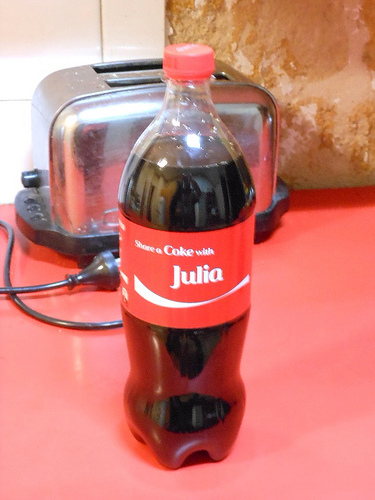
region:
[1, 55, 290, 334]
Toaster sitting on a red counter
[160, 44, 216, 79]
Red lid on Coke bottle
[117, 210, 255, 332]
Red and white label on Coke bottle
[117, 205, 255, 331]
Name on side of Coke bottle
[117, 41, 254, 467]
Coke bottle sitting on red counter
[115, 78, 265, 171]
Drops of Coke inside bottle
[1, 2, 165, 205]
White tiles on wall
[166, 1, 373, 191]
Brown backsplash behind toaster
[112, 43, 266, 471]
Clear plastic bottle sitting on counter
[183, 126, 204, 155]
Light reflection shining off of bottle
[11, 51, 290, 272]
chrome electrical toaster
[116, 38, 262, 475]
soda bottle with personalized label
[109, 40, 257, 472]
coca cola bottle is full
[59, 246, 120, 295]
electrical plug on a toaster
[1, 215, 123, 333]
black toaster cable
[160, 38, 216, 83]
red plastic lid of a soda bottle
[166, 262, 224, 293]
the name Julia printed on a soda bottle label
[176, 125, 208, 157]
light reflected in a soda bottle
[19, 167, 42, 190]
toast setting dial on a toaster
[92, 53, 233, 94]
slots in the top of a toaster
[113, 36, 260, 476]
A bottle of Coke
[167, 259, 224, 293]
The name "Julia" on a bottle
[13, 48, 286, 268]
Silver and black toaster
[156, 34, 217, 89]
A red bottle cap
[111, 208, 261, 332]
Red label on the bottle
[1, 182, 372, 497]
A red colored countertop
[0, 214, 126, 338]
Black plug and wire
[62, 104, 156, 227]
Reflections on the toaster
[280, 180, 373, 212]
Shadow on the counter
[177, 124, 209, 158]
Light glare on the bottle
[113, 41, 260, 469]
Full coke bottle.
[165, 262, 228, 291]
Name Julia on coke bottle.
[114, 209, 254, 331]
Red and white label.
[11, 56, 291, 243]
Stainless steel toaster.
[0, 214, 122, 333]
Cord to a toaster.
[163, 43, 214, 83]
Cap of coke bottle.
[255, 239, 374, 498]
Red table top.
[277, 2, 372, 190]
Rock concrete wall.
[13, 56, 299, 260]
Two slice toaster.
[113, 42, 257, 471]
Red and white personalized Julia Coca Cola bottle.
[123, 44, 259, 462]
Bottle of coke on table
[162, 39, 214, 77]
Red top of bottle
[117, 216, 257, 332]
Red sticker on bottle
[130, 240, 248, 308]
White writing on label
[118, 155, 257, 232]
Dark liquid in a bottle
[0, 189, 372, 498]
Red colored surface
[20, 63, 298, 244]
Silver colored electric box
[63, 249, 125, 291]
Black colored electrical plug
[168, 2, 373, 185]
Brown colored part of wall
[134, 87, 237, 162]
Empty part of a bottle